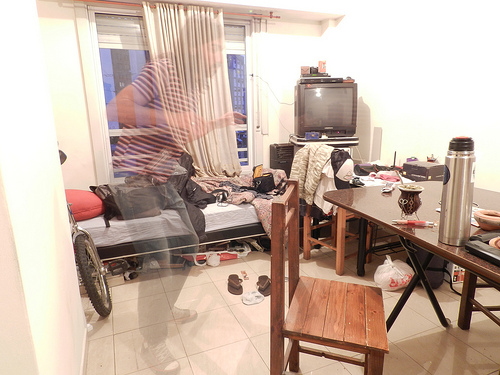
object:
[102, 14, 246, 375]
transparent image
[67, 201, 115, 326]
bicycle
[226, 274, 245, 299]
brown flip-flop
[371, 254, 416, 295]
plastic bag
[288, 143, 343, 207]
clothing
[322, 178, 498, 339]
dark table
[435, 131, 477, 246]
black thermos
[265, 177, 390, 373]
wooden chair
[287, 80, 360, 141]
television near wall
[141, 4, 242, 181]
curtain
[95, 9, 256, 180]
window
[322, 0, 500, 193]
wall is white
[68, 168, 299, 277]
bed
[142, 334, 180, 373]
person has shoe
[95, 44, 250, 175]
sky is blue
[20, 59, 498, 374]
room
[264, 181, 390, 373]
chair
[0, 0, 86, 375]
wall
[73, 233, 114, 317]
wheel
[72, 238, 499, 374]
floor